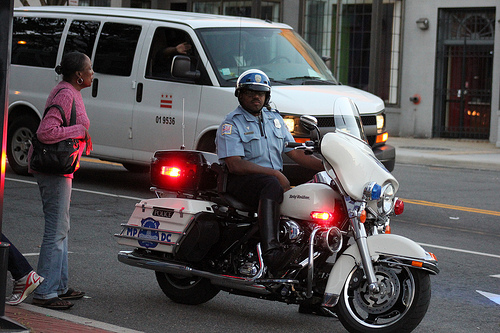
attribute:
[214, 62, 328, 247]
man — black, brown, sitting, looking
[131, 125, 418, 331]
bike — white, on, running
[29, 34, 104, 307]
woman — brown, standing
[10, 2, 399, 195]
van — white, big, long, wide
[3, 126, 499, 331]
road — grey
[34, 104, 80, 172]
bag — black, short